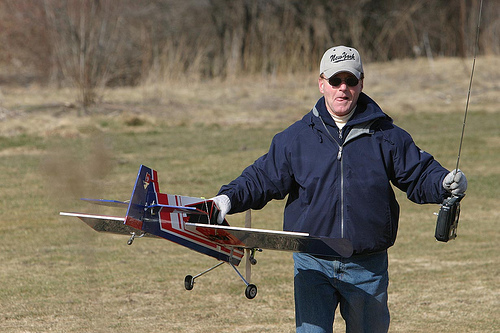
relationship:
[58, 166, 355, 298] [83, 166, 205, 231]
airplane has tail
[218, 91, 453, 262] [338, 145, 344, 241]
jacket has zipper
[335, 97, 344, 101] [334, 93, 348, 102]
tongue sticks out mouth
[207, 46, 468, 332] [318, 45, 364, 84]
man wears hat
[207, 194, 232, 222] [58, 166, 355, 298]
hand holds airplane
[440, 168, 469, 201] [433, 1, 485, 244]
hand holds remote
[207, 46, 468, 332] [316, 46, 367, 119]
man has head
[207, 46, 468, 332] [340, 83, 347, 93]
man has nose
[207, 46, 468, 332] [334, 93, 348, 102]
man has mouth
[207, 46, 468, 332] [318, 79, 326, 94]
man has ear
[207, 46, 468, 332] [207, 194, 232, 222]
man has hand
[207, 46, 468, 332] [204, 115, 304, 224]
man has arm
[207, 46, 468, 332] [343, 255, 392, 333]
man has leg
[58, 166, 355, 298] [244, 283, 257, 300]
airplane has wheel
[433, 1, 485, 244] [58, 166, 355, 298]
remote for airplane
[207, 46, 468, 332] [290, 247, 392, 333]
man has jeans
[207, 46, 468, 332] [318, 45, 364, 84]
man has hat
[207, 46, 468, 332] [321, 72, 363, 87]
man has sunglasses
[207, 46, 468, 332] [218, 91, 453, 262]
man wears jacket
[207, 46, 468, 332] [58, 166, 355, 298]
man carries airplane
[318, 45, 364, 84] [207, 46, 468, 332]
cap on man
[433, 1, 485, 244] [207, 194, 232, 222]
remote in hand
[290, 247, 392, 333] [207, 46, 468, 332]
jeans on man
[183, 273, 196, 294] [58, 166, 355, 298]
wheel on airplane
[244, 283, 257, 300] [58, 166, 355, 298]
wheel on airplane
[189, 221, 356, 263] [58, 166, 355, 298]
wing on airplane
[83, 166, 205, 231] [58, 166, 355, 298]
wing on airplane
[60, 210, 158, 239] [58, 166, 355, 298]
wing on airplane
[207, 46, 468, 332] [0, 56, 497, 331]
man standing in field